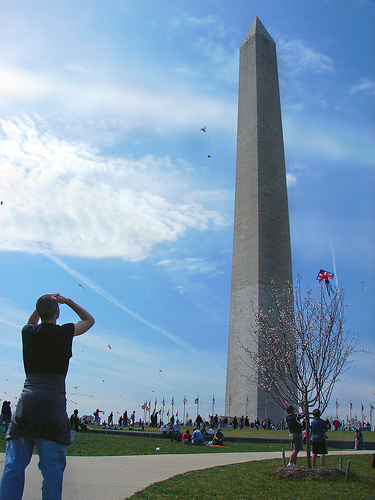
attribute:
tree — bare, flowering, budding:
[233, 274, 374, 469]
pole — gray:
[344, 460, 352, 484]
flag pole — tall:
[194, 395, 200, 418]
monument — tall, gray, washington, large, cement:
[225, 15, 300, 427]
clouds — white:
[1, 109, 233, 264]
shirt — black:
[21, 321, 76, 377]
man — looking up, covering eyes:
[1, 293, 96, 499]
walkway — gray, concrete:
[1, 449, 375, 498]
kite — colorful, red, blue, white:
[315, 268, 337, 298]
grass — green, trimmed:
[1, 425, 374, 500]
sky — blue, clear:
[1, 0, 373, 427]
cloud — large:
[1, 161, 229, 264]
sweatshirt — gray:
[5, 371, 72, 446]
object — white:
[155, 446, 161, 453]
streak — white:
[40, 250, 200, 356]